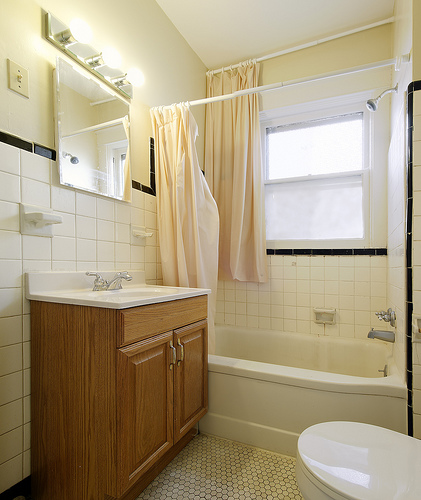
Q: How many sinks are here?
A: 1.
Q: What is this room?
A: A bathroom.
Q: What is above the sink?
A: A mirror.